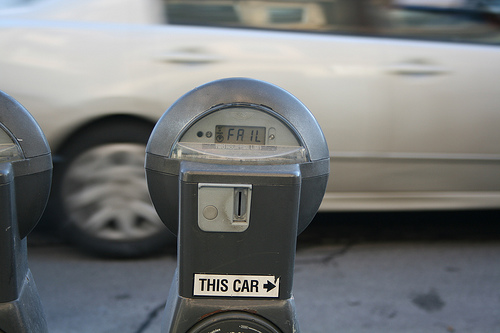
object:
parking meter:
[145, 79, 329, 333]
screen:
[210, 124, 269, 145]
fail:
[225, 127, 263, 144]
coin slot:
[230, 189, 247, 219]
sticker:
[191, 271, 279, 298]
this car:
[197, 275, 260, 294]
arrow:
[262, 278, 277, 294]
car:
[5, 0, 500, 254]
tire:
[45, 133, 181, 260]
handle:
[155, 47, 222, 68]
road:
[370, 249, 464, 305]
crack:
[135, 305, 164, 330]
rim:
[68, 142, 171, 243]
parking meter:
[0, 90, 54, 333]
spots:
[406, 286, 450, 315]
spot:
[340, 293, 365, 311]